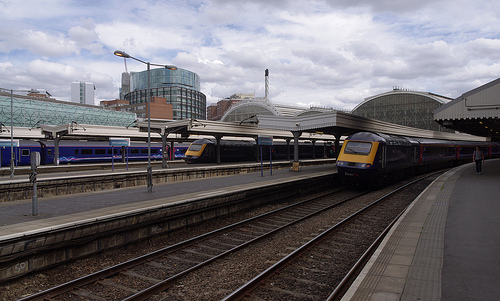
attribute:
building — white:
[176, 32, 422, 154]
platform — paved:
[344, 156, 497, 297]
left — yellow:
[183, 140, 216, 162]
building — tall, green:
[115, 38, 211, 139]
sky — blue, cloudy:
[2, 2, 498, 107]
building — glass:
[121, 66, 206, 118]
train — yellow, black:
[335, 130, 499, 179]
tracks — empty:
[219, 188, 452, 297]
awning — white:
[428, 76, 498, 138]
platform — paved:
[361, 163, 498, 299]